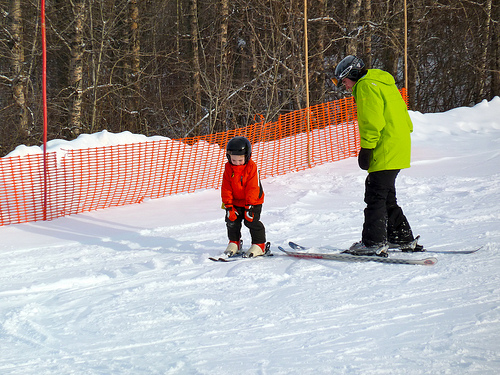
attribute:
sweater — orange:
[228, 163, 260, 205]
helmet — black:
[217, 134, 253, 155]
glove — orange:
[231, 205, 262, 221]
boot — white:
[248, 236, 271, 250]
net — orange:
[41, 143, 87, 190]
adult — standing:
[334, 41, 418, 273]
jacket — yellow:
[357, 76, 410, 169]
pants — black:
[364, 174, 418, 248]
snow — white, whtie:
[92, 272, 143, 308]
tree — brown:
[183, 28, 225, 62]